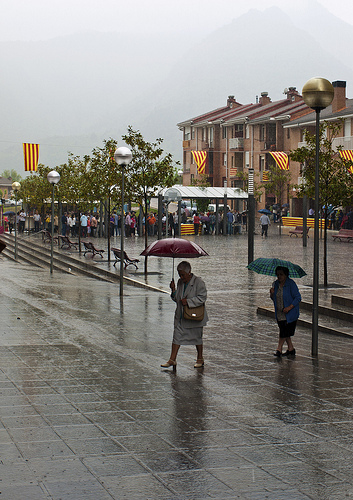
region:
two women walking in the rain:
[132, 235, 309, 396]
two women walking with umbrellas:
[129, 219, 331, 379]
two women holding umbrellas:
[134, 225, 311, 378]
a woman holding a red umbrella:
[138, 232, 220, 379]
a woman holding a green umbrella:
[250, 249, 309, 362]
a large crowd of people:
[12, 197, 198, 236]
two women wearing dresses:
[138, 230, 317, 378]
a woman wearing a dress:
[155, 253, 221, 372]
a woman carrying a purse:
[159, 260, 208, 386]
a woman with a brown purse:
[156, 255, 211, 376]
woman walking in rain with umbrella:
[140, 235, 208, 370]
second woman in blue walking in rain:
[243, 256, 306, 355]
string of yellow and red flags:
[0, 138, 350, 174]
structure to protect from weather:
[162, 184, 244, 235]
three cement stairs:
[256, 292, 351, 337]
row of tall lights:
[12, 146, 131, 289]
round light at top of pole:
[117, 146, 131, 166]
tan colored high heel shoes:
[159, 355, 203, 368]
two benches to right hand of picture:
[287, 224, 351, 242]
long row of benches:
[40, 228, 138, 270]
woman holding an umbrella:
[139, 221, 225, 385]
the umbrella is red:
[134, 223, 215, 275]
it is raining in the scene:
[1, 2, 348, 498]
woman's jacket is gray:
[154, 254, 211, 342]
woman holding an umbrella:
[252, 244, 315, 362]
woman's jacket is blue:
[251, 270, 306, 331]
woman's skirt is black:
[262, 312, 298, 343]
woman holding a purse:
[165, 254, 214, 327]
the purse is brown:
[176, 291, 211, 324]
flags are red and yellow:
[13, 138, 349, 176]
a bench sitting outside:
[112, 239, 136, 270]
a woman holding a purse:
[177, 285, 213, 327]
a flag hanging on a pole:
[185, 143, 213, 182]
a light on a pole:
[105, 138, 139, 189]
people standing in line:
[123, 206, 143, 236]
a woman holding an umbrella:
[143, 229, 211, 295]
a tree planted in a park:
[315, 154, 341, 282]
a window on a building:
[256, 125, 270, 153]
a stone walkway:
[60, 395, 169, 468]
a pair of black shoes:
[267, 340, 304, 366]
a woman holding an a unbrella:
[139, 168, 258, 382]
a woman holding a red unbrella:
[146, 203, 239, 371]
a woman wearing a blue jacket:
[247, 265, 307, 357]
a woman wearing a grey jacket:
[155, 242, 241, 326]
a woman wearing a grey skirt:
[143, 242, 252, 352]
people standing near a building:
[50, 121, 334, 245]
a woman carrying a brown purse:
[177, 252, 220, 326]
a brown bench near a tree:
[100, 235, 143, 281]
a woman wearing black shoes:
[232, 334, 310, 371]